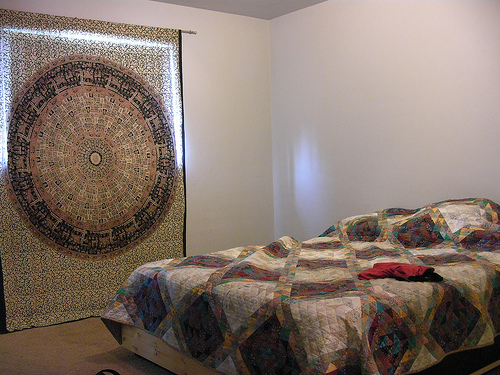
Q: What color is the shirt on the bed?
A: Red.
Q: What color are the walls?
A: White.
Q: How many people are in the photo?
A: None.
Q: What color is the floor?
A: Brown.